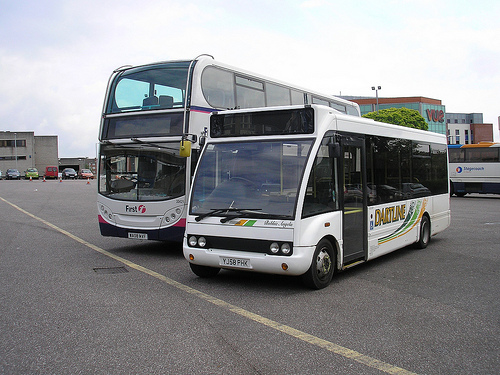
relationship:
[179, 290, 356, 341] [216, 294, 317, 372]
line on a concrete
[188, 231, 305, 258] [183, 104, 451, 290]
headlights on bus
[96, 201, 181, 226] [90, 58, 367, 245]
lights on front of bus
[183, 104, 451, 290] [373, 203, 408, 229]
bus saying dartline